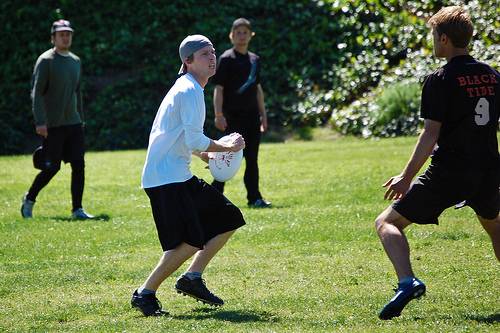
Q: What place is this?
A: It is a field.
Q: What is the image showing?
A: It is showing a field.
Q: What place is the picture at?
A: It is at the field.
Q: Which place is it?
A: It is a field.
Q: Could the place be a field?
A: Yes, it is a field.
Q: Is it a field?
A: Yes, it is a field.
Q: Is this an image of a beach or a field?
A: It is showing a field.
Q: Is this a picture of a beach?
A: No, the picture is showing a field.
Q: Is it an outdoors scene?
A: Yes, it is outdoors.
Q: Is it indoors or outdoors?
A: It is outdoors.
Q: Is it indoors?
A: No, it is outdoors.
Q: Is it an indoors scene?
A: No, it is outdoors.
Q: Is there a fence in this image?
A: No, there are no fences.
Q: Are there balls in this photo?
A: Yes, there is a ball.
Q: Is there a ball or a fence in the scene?
A: Yes, there is a ball.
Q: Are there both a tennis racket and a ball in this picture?
A: No, there is a ball but no rackets.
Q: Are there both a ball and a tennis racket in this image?
A: No, there is a ball but no rackets.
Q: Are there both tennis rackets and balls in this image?
A: No, there is a ball but no rackets.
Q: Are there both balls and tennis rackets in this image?
A: No, there is a ball but no rackets.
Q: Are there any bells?
A: No, there are no bells.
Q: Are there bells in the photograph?
A: No, there are no bells.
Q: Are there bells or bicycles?
A: No, there are no bells or bicycles.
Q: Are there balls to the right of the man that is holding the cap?
A: Yes, there is a ball to the right of the man.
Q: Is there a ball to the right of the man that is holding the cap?
A: Yes, there is a ball to the right of the man.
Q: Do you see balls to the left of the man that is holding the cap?
A: No, the ball is to the right of the man.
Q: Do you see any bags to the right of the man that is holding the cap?
A: No, there is a ball to the right of the man.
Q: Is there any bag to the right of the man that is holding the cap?
A: No, there is a ball to the right of the man.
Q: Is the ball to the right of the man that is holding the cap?
A: Yes, the ball is to the right of the man.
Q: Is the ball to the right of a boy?
A: No, the ball is to the right of the man.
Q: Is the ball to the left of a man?
A: No, the ball is to the right of a man.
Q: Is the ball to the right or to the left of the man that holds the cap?
A: The ball is to the right of the man.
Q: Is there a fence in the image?
A: No, there are no fences.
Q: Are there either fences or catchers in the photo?
A: No, there are no fences or catchers.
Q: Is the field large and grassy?
A: Yes, the field is large and grassy.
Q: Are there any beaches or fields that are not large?
A: No, there is a field but it is large.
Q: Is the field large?
A: Yes, the field is large.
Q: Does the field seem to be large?
A: Yes, the field is large.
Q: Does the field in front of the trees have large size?
A: Yes, the field is large.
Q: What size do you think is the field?
A: The field is large.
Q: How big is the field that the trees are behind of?
A: The field is large.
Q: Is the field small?
A: No, the field is large.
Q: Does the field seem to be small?
A: No, the field is large.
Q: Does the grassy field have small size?
A: No, the field is large.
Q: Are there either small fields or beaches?
A: No, there is a field but it is large.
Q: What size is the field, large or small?
A: The field is large.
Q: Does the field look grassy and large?
A: Yes, the field is grassy and large.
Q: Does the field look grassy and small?
A: No, the field is grassy but large.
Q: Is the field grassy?
A: Yes, the field is grassy.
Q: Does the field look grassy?
A: Yes, the field is grassy.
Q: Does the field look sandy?
A: No, the field is grassy.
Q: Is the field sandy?
A: No, the field is grassy.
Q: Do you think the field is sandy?
A: No, the field is grassy.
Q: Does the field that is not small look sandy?
A: No, the field is grassy.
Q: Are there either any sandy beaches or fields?
A: No, there is a field but it is grassy.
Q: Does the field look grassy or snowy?
A: The field is grassy.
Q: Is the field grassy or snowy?
A: The field is grassy.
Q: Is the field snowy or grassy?
A: The field is grassy.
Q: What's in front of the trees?
A: The field is in front of the trees.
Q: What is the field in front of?
A: The field is in front of the trees.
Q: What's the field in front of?
A: The field is in front of the trees.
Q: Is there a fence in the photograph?
A: No, there are no fences.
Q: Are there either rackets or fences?
A: No, there are no fences or rackets.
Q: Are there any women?
A: No, there are no women.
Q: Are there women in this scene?
A: No, there are no women.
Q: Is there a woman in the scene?
A: No, there are no women.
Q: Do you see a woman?
A: No, there are no women.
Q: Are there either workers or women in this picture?
A: No, there are no women or workers.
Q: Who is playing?
A: The men are playing.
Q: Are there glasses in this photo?
A: No, there are no glasses.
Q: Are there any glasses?
A: No, there are no glasses.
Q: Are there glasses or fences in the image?
A: No, there are no glasses or fences.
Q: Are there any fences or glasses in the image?
A: No, there are no glasses or fences.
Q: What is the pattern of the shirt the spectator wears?
A: The shirt is striped.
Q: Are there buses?
A: No, there are no buses.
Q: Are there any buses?
A: No, there are no buses.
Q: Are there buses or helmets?
A: No, there are no buses or helmets.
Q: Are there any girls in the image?
A: No, there are no girls.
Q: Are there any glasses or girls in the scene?
A: No, there are no girls or glasses.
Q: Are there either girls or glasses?
A: No, there are no girls or glasses.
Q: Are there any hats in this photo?
A: Yes, there is a hat.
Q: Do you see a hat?
A: Yes, there is a hat.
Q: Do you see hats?
A: Yes, there is a hat.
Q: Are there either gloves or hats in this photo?
A: Yes, there is a hat.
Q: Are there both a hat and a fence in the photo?
A: No, there is a hat but no fences.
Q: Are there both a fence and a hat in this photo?
A: No, there is a hat but no fences.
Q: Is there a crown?
A: No, there are no crowns.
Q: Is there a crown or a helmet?
A: No, there are no crowns or helmets.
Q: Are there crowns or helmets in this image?
A: No, there are no crowns or helmets.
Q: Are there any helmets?
A: No, there are no helmets.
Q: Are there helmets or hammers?
A: No, there are no helmets or hammers.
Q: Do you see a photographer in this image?
A: No, there are no photographers.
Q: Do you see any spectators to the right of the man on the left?
A: Yes, there is a spectator to the right of the man.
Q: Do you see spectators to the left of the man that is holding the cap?
A: No, the spectator is to the right of the man.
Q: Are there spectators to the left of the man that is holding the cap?
A: No, the spectator is to the right of the man.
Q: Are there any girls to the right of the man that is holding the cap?
A: No, there is a spectator to the right of the man.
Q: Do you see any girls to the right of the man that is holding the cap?
A: No, there is a spectator to the right of the man.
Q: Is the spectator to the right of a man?
A: Yes, the spectator is to the right of a man.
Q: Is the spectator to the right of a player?
A: No, the spectator is to the right of a man.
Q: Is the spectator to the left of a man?
A: No, the spectator is to the right of a man.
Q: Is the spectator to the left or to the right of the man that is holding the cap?
A: The spectator is to the right of the man.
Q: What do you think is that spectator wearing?
A: The spectator is wearing a shirt.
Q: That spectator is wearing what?
A: The spectator is wearing a shirt.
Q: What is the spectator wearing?
A: The spectator is wearing a shirt.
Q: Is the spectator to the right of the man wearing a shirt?
A: Yes, the spectator is wearing a shirt.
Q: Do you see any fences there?
A: No, there are no fences.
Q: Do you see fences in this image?
A: No, there are no fences.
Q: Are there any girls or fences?
A: No, there are no fences or girls.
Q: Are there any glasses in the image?
A: No, there are no glasses.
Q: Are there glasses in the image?
A: No, there are no glasses.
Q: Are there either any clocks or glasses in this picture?
A: No, there are no glasses or clocks.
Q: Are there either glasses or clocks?
A: No, there are no glasses or clocks.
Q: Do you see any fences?
A: No, there are no fences.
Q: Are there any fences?
A: No, there are no fences.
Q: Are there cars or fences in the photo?
A: No, there are no fences or cars.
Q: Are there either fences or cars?
A: No, there are no fences or cars.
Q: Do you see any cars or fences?
A: No, there are no fences or cars.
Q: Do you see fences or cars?
A: No, there are no fences or cars.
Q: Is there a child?
A: No, there are no children.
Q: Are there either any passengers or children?
A: No, there are no children or passengers.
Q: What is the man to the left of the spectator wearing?
A: The man is wearing a shirt.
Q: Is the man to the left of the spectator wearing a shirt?
A: Yes, the man is wearing a shirt.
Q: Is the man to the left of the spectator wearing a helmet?
A: No, the man is wearing a shirt.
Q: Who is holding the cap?
A: The man is holding the cap.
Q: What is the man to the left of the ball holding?
A: The man is holding the cap.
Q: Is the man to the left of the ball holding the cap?
A: Yes, the man is holding the cap.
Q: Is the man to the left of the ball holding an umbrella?
A: No, the man is holding the cap.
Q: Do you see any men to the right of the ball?
A: No, the man is to the left of the ball.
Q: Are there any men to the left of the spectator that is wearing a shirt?
A: Yes, there is a man to the left of the spectator.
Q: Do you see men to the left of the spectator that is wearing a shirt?
A: Yes, there is a man to the left of the spectator.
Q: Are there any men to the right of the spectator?
A: No, the man is to the left of the spectator.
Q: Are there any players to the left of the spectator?
A: No, there is a man to the left of the spectator.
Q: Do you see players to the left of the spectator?
A: No, there is a man to the left of the spectator.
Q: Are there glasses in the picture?
A: No, there are no glasses.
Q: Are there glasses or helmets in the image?
A: No, there are no glasses or helmets.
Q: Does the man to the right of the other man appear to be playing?
A: Yes, the man is playing.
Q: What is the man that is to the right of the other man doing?
A: The man is playing.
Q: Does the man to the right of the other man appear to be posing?
A: No, the man is playing.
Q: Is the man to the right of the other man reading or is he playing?
A: The man is playing.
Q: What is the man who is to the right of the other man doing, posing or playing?
A: The man is playing.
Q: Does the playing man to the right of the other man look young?
A: Yes, the man is young.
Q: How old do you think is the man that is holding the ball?
A: The man is young.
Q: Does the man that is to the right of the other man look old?
A: No, the man is young.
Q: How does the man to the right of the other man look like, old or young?
A: The man is young.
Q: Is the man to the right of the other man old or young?
A: The man is young.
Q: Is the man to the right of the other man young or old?
A: The man is young.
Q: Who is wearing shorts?
A: The man is wearing shorts.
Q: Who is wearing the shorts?
A: The man is wearing shorts.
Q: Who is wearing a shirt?
A: The man is wearing a shirt.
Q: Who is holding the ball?
A: The man is holding the ball.